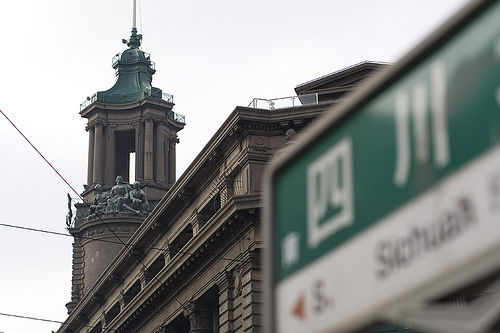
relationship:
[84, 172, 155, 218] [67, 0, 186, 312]
statue on building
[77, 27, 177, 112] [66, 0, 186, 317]
roof on tower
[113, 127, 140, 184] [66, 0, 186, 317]
window in tower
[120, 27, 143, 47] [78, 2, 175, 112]
statue on roof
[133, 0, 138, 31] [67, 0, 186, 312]
steeple on building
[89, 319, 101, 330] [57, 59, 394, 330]
window on building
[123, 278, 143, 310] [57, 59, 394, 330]
window on building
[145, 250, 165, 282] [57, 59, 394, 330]
window on building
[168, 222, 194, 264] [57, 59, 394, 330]
window on building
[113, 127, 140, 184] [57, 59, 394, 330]
window on building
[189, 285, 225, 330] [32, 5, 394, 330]
window on building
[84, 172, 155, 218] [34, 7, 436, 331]
statue on building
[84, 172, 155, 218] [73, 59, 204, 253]
statue on building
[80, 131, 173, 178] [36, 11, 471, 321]
pillars on building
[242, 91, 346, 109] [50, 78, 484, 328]
railing on building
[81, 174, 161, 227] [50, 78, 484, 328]
man on building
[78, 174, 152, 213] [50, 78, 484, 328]
woman on building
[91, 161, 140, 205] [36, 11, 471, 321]
man on building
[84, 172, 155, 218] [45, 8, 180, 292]
statue on tower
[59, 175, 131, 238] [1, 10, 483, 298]
deck on building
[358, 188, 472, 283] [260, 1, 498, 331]
word on sign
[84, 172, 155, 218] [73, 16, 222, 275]
statue on tower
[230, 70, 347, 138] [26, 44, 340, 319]
railing on building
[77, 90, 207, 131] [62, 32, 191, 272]
railing on tower